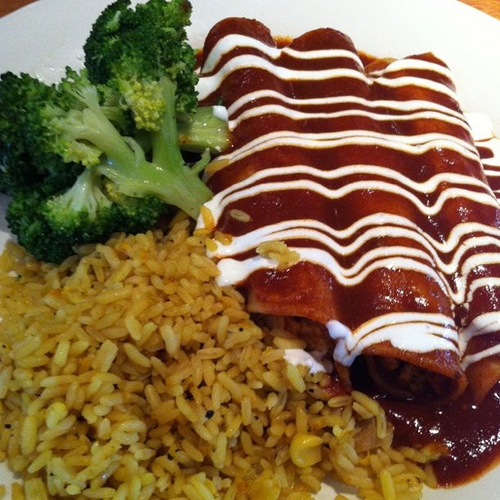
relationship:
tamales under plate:
[216, 46, 463, 364] [420, 9, 484, 41]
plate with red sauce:
[1, 0, 498, 498] [371, 383, 498, 490]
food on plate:
[0, 0, 499, 498] [1, 0, 498, 498]